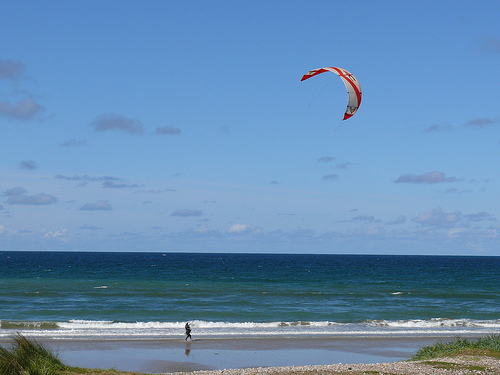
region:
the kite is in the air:
[293, 64, 379, 132]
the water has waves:
[237, 318, 269, 330]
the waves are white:
[95, 318, 118, 331]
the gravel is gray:
[390, 361, 417, 373]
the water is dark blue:
[291, 251, 312, 261]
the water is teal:
[315, 282, 340, 292]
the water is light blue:
[325, 300, 346, 310]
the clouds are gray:
[422, 170, 442, 181]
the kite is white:
[345, 86, 355, 101]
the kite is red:
[345, 74, 358, 93]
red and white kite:
[300, 61, 365, 117]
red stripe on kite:
[266, 54, 383, 129]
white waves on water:
[72, 289, 294, 332]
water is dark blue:
[167, 275, 292, 313]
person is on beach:
[177, 321, 199, 341]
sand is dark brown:
[236, 335, 318, 362]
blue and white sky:
[0, 93, 171, 221]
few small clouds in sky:
[23, 98, 193, 211]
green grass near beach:
[417, 327, 492, 373]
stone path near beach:
[326, 341, 488, 373]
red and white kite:
[265, 57, 365, 137]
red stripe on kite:
[301, 52, 361, 133]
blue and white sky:
[37, 54, 300, 237]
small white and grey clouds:
[26, 61, 298, 236]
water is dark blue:
[72, 254, 259, 314]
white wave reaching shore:
[108, 316, 470, 347]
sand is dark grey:
[220, 341, 416, 365]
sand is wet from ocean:
[215, 338, 296, 366]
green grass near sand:
[399, 327, 495, 353]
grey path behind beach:
[197, 336, 479, 370]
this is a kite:
[290, 42, 388, 137]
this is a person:
[165, 297, 217, 367]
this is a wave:
[202, 312, 247, 342]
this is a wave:
[258, 300, 332, 356]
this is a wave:
[349, 316, 401, 346]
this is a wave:
[69, 317, 135, 357]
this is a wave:
[122, 305, 194, 350]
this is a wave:
[359, 300, 424, 355]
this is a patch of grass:
[9, 326, 53, 373]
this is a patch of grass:
[415, 323, 497, 370]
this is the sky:
[117, 60, 220, 137]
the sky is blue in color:
[119, 36, 269, 132]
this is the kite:
[290, 57, 365, 130]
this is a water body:
[232, 257, 322, 289]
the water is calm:
[244, 257, 314, 278]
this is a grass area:
[449, 328, 497, 352]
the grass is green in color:
[31, 340, 58, 373]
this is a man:
[180, 315, 196, 347]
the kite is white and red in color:
[333, 65, 364, 97]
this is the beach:
[242, 335, 327, 373]